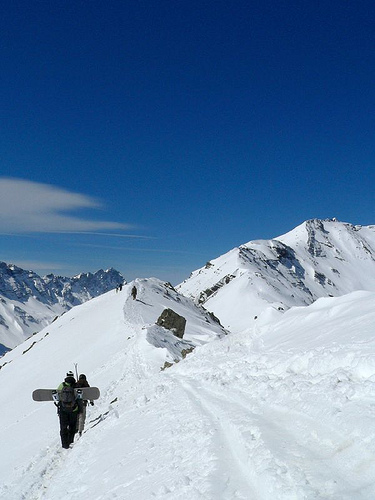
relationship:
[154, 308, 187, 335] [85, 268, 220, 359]
boulder on mountain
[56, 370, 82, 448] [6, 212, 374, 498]
man on mountain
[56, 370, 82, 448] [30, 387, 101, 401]
man holding snowboard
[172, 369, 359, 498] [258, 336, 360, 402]
tracks in snow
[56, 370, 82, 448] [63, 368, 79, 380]
man wearing hat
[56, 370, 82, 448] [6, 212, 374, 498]
man hiking up mountain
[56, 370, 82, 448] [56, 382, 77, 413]
man wearing backpack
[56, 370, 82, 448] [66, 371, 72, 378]
man wearing hat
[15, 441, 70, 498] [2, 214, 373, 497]
foot prints in snow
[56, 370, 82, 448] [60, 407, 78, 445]
man wearing pants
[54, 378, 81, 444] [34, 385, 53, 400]
man holding snow board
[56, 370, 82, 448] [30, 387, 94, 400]
man carrying snow board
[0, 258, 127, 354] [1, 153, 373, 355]
mountain in background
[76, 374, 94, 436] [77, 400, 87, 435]
men wearing pants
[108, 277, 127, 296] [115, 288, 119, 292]
person wearing pants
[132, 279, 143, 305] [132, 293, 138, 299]
person wearing pants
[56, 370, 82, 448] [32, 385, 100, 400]
man carrying snowboard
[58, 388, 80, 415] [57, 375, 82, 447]
back pack on person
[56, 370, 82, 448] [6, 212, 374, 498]
man walking up mountain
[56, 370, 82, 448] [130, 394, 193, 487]
man in ice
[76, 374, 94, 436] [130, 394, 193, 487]
men in ice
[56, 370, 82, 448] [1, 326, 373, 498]
man walking in ice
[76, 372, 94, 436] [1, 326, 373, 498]
men walking in ice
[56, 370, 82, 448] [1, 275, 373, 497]
man standing in ice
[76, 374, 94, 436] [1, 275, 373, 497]
men standing in ice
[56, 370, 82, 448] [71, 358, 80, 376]
man holding stick